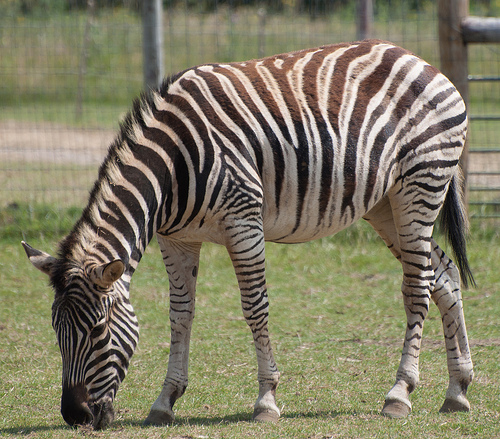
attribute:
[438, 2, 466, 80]
post — Wooden 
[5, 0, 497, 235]
fence — METAL 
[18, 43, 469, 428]
zebra — BLACK, WHITE, awake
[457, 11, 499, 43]
top — Wooden 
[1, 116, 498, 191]
road — DIRT 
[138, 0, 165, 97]
poles — METAL 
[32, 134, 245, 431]
hooves — brown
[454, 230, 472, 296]
haired tail — black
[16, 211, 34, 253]
rails — metal